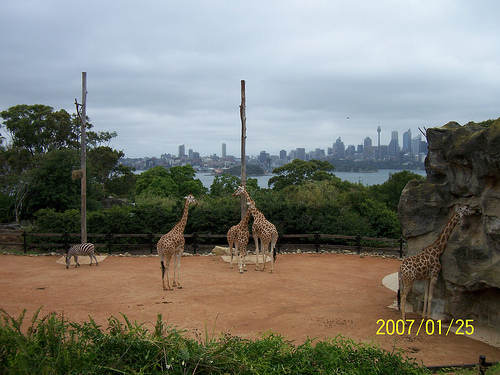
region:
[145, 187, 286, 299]
three giraffe's in enclosure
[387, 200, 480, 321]
giraffe near rock face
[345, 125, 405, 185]
city skyline beyond water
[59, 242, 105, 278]
zebra with face to ground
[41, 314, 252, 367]
green vegetation in foreground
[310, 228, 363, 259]
wood fence around enclosure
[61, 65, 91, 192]
pole with giraffe food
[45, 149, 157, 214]
trees behind zoo enclosure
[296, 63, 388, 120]
gray cloudy daytime sky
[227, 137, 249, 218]
pole behind two giraffes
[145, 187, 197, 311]
Giraffe is standing on dry ground.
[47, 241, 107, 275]
Zebra has his head bent.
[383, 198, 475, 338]
Giraffe is standing by rock structure.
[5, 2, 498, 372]
Animals are not in their natural habitat.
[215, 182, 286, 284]
Two giraffes are standing together.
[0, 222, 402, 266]
Wood fence surrounds area.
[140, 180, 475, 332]
There are four giraffes.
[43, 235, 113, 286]
There is only one zebra visible.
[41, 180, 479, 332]
There are five animals visible altogether.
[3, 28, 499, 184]
The air is full of smog.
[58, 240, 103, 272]
a zebra is grazing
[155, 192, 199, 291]
a giraffe standing alone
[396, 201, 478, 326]
a giraffe by a rock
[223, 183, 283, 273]
a giraffe taller than the giraffe beside it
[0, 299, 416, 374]
green shrub by a fence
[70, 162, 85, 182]
a bale of hay hanging on a rope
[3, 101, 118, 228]
green trees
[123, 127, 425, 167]
many sky scrapers on the horizon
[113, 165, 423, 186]
a body of water by the city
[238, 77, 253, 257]
a pole beside giraffes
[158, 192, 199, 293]
very tall giraffe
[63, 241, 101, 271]
black and white zebra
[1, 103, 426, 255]
green trees and bushes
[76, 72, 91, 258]
tall wooden polls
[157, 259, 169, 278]
black tail of giraffe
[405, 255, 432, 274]
brown spots on giraffe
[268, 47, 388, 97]
white clouds in the sky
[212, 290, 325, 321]
red clay ground of zoo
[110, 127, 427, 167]
buildings in the background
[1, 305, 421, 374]
plants behind the giraffes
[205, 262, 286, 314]
the sand is brown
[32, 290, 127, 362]
the plants are green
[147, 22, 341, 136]
the sky is cloudy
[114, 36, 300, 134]
the clouds are dark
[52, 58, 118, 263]
the pole is tall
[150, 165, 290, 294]
there are many giraffes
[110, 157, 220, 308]
the giraffe is standing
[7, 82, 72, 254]
the tree is tall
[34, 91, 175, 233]
there are many trees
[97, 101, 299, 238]
the trees are tall